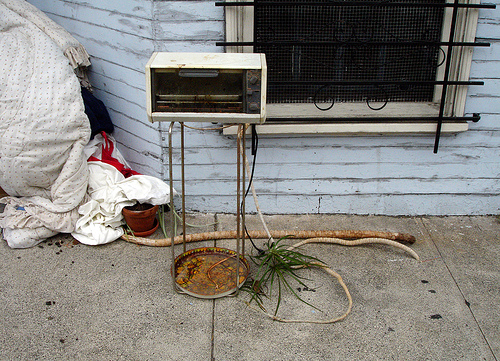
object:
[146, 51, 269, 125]
toaster oven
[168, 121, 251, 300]
plant stand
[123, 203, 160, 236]
pot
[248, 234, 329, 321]
plant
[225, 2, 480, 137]
window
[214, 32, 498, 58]
security bars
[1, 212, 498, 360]
sidewalk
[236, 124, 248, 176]
rust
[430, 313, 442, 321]
stain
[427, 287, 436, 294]
stain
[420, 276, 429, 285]
stain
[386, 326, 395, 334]
stain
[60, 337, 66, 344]
stain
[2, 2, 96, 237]
clothing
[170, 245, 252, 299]
tray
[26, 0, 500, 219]
house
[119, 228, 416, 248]
wood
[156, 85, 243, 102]
sheet